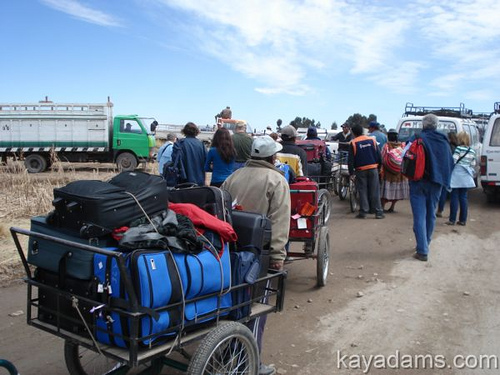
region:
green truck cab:
[105, 103, 160, 175]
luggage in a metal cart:
[12, 170, 284, 371]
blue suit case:
[91, 226, 236, 354]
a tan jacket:
[217, 156, 295, 277]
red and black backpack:
[401, 130, 426, 184]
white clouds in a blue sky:
[148, 1, 496, 95]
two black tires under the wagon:
[61, 316, 265, 374]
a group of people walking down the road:
[152, 108, 477, 272]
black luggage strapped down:
[50, 158, 174, 236]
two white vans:
[395, 104, 497, 198]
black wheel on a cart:
[188, 318, 275, 373]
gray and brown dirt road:
[361, 257, 468, 352]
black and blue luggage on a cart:
[14, 179, 281, 344]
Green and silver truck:
[8, 98, 174, 179]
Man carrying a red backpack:
[405, 107, 459, 279]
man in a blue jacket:
[388, 111, 481, 287]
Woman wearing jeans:
[449, 130, 488, 230]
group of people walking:
[164, 112, 497, 279]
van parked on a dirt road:
[393, 96, 481, 198]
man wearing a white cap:
[229, 127, 347, 285]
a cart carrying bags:
[33, 179, 267, 364]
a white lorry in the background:
[5, 96, 130, 171]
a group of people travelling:
[6, 92, 482, 317]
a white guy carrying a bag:
[418, 131, 448, 277]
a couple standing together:
[164, 137, 251, 181]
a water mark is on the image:
[338, 352, 490, 372]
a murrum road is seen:
[379, 209, 499, 366]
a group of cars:
[175, 107, 472, 167]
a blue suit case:
[102, 250, 218, 308]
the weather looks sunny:
[68, 123, 478, 362]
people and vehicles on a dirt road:
[40, 36, 463, 336]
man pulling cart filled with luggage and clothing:
[10, 125, 312, 361]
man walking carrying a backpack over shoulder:
[386, 105, 457, 265]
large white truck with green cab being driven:
[15, 90, 160, 171]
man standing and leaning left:
[326, 95, 386, 230]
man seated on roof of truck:
[197, 95, 247, 140]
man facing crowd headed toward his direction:
[247, 100, 402, 230]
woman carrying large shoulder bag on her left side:
[147, 116, 212, 191]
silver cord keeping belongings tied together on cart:
[65, 151, 250, 363]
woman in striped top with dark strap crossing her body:
[447, 111, 478, 238]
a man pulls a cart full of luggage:
[11, 133, 294, 373]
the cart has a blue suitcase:
[19, 174, 266, 374]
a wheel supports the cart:
[160, 312, 292, 374]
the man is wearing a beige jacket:
[228, 135, 291, 250]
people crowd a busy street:
[24, 114, 471, 363]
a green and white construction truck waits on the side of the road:
[3, 103, 158, 164]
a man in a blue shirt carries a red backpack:
[399, 106, 453, 270]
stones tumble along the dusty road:
[342, 269, 402, 318]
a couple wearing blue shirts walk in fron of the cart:
[163, 119, 236, 185]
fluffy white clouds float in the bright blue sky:
[223, 15, 423, 86]